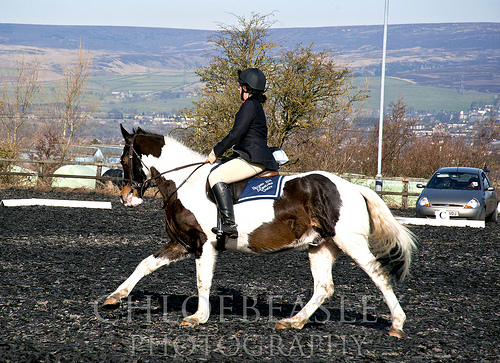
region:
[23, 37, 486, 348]
A silver car is in the background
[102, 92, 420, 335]
A horse is in the photo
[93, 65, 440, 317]
A person is riding the horse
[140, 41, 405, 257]
A person is wearing a black helmet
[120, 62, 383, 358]
A person is wearing black boots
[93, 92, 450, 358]
The horse is white and brown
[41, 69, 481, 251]
Grass is in the background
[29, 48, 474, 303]
Photo was taken during the day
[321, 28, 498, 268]
A pole is next to the car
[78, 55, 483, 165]
Houses are in the background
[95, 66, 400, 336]
rider on back of horse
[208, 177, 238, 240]
black leather boot on rider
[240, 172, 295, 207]
blue blanket with white letters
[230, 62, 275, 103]
black helmet on head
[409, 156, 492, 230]
parked car behind white curb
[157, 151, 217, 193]
hand on horse's reign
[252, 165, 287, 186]
brown saddle on horse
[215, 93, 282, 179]
black jacket on rider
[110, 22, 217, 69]
hazy hill on horizon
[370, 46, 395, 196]
metal pole behind fence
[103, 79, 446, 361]
horse is brown and white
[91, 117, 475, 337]
horse is brown and white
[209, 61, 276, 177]
this is a man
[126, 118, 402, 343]
the man is riding on a horse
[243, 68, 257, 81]
this is a helmet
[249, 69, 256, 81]
the helmet is black in color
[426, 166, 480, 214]
this is a car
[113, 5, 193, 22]
this is the sky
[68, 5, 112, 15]
the sky is blue in color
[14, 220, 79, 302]
this is a ground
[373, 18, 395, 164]
this is a pole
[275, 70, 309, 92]
the tree has green leaves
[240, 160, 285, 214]
Blue saddle cloth with white writing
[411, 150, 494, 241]
Silver car with white and orange lights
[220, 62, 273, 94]
Black riding hat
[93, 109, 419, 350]
Dark brown and white horse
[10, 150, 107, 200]
Wooden fence in the background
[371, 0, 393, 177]
Tall silver pole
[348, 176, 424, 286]
White horse's tail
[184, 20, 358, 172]
Yellow and green tree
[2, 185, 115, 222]
White parking marker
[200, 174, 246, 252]
Tall black riding boot